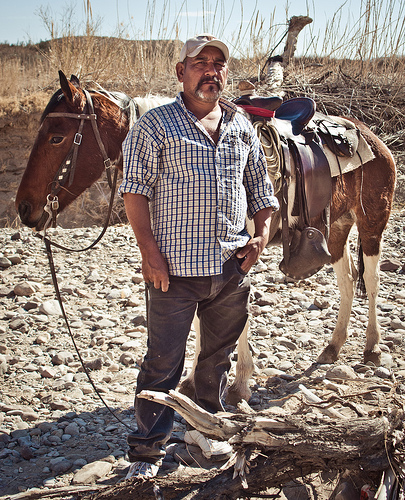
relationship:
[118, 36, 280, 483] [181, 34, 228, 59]
man wearing cap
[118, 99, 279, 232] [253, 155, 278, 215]
shirt has sleeve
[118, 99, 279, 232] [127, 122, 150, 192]
shirt has sleeve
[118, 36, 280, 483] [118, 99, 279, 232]
man wearing shirt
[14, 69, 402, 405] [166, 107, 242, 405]
horse belongs to man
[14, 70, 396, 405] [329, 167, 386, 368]
horse has legs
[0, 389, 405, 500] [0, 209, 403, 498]
logs on ground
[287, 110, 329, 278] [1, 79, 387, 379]
saddle on horse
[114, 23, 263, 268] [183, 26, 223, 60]
man in cap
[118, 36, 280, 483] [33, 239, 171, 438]
man holding strap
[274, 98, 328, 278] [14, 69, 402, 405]
saddle on horse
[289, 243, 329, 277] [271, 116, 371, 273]
holder hanging from straps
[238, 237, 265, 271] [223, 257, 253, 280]
hand in pocket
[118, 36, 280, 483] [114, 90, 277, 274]
man wearing shirt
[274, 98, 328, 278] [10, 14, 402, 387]
saddle laying across horse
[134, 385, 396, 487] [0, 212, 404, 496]
logs laying on rocky ground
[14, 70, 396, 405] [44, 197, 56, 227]
horse biting on bit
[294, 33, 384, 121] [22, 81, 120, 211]
weed behind horse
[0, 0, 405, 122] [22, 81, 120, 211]
weed behind horse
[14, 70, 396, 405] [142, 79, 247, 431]
horse behind man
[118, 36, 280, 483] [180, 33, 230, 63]
man wearing cap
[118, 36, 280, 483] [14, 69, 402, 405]
man standing in front of horse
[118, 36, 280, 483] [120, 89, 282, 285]
man wearing shirt